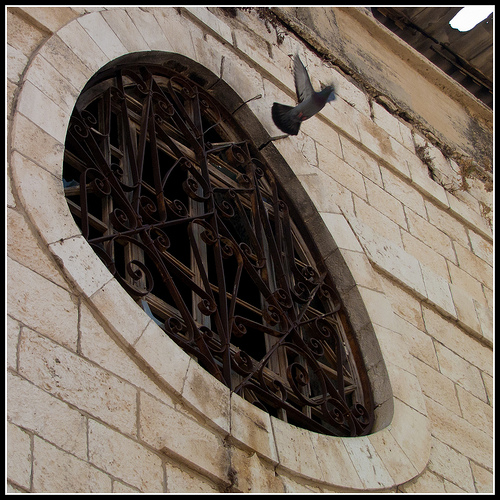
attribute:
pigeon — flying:
[269, 62, 352, 146]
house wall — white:
[374, 145, 454, 225]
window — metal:
[96, 67, 401, 430]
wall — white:
[369, 180, 446, 235]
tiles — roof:
[382, 6, 494, 92]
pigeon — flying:
[269, 48, 336, 133]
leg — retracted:
[296, 110, 304, 119]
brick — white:
[376, 159, 432, 228]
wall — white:
[8, 5, 495, 498]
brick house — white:
[12, 364, 162, 499]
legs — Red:
[297, 110, 309, 124]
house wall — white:
[9, 22, 74, 322]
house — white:
[3, 3, 492, 493]